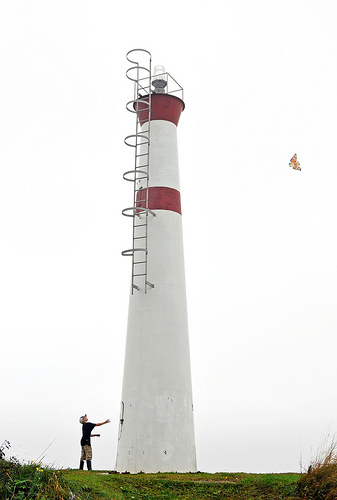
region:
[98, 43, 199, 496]
Lighthouse has a short ladder for safety.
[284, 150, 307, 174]
Multi color kite in the sky for fun.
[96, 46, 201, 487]
Red stripes for safety so planes can see it.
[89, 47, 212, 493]
Light house has a light that is not on.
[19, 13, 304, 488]
A fogging climate with the sun hidden.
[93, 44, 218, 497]
Side door into light house for maintenance.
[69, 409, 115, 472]
Your boy flying a kite.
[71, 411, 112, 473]
Your boy with a baseball cap on.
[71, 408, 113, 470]
Black water boots to keep feet dry.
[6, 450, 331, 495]
Green grassy bank with little yellow flowers.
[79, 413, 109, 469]
Young boy flying kite near lighthouse.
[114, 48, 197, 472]
Young boy flying kite near lighthouse.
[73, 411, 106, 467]
person is near lighthouse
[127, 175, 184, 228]
red stripe on lighthouse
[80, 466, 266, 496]
green grass under lighthouse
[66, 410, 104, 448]
person has black shirt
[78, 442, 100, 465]
person has tan pants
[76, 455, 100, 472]
person has black boots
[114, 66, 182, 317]
metal ladder on lighthouse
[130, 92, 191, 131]
lighthouse has red top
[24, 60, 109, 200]
white and grey clouds in sky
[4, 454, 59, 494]
green bushes behind man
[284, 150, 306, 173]
A bird flying in the sky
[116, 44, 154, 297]
Silver ladder on side of lighthouse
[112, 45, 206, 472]
Red and white lighthouse in field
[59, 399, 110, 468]
boy looking at top of lighthouse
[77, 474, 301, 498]
green grass near lighthouse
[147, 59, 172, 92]
big light on top of lighthouse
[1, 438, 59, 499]
vegetation near building structure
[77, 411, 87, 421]
white hat on boy's head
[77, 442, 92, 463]
brown pants on boy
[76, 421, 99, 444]
black t-shirt on boy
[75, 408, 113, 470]
Man wearing a black shirt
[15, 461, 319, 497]
The grass is green with bushes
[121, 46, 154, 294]
Silver railing on light house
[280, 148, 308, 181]
The kite is orange and black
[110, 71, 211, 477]
The light house is white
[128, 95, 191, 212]
The light house has red stripes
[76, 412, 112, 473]
The man is wearing a hat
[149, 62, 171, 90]
Clear light on top of light house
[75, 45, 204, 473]
The man is next to the light house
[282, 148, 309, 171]
The kite is in the air